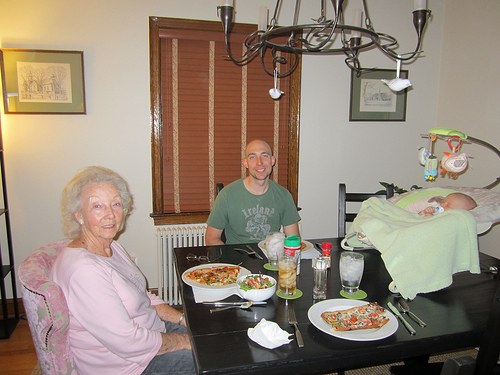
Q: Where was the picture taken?
A: Dining room.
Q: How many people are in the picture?
A: Three.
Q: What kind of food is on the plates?
A: Pizza.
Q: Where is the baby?
A: Bouncy seat.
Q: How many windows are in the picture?
A: One.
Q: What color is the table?
A: Black.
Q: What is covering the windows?
A: Blinds.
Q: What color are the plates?
A: White.